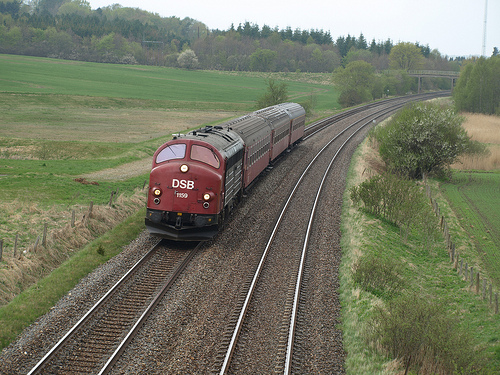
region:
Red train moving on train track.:
[137, 65, 313, 260]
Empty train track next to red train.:
[227, 180, 312, 366]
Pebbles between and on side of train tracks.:
[133, 279, 239, 370]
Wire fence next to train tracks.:
[8, 187, 126, 257]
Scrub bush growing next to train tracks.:
[351, 178, 463, 374]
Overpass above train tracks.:
[381, 61, 477, 94]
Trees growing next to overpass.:
[198, 13, 348, 88]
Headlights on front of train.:
[148, 181, 220, 203]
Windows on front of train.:
[152, 138, 226, 177]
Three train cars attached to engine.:
[224, 98, 307, 186]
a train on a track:
[144, 98, 305, 239]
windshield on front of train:
[154, 138, 220, 166]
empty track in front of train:
[26, 235, 204, 372]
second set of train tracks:
[218, 176, 321, 372]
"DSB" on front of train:
[172, 178, 195, 188]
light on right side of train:
[151, 187, 160, 198]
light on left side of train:
[203, 191, 209, 200]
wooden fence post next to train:
[1, 178, 146, 270]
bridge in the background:
[410, 64, 467, 91]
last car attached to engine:
[282, 95, 310, 147]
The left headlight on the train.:
[150, 187, 162, 198]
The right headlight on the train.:
[197, 189, 215, 201]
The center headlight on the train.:
[178, 163, 190, 171]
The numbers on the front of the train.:
[173, 191, 193, 203]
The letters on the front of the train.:
[171, 177, 196, 192]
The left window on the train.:
[155, 140, 186, 165]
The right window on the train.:
[186, 142, 218, 164]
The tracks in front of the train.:
[41, 225, 176, 371]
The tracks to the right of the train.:
[247, 107, 342, 372]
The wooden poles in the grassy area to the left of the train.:
[5, 162, 147, 267]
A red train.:
[127, 52, 317, 269]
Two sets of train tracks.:
[68, 244, 369, 358]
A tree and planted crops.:
[381, 104, 498, 244]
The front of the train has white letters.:
[152, 139, 221, 214]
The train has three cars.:
[219, 84, 349, 193]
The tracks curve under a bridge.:
[279, 32, 483, 153]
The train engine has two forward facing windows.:
[148, 122, 254, 200]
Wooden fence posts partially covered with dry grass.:
[16, 178, 129, 270]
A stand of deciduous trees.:
[66, 28, 350, 80]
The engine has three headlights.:
[142, 137, 245, 221]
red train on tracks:
[134, 129, 236, 251]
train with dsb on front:
[163, 176, 205, 206]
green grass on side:
[352, 247, 412, 313]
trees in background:
[172, 49, 199, 71]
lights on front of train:
[147, 182, 216, 245]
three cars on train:
[206, 78, 319, 190]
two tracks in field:
[77, 284, 300, 337]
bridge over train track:
[398, 55, 463, 100]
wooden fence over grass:
[428, 219, 470, 275]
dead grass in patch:
[468, 112, 484, 135]